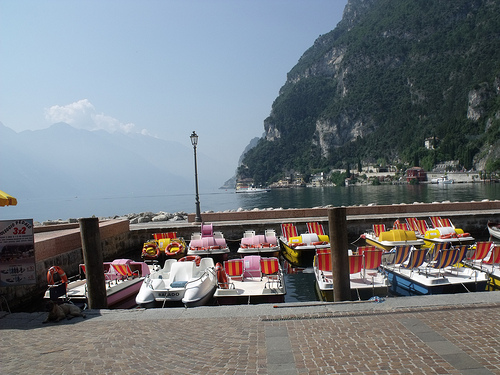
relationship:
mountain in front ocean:
[221, 1, 496, 188] [0, 186, 499, 217]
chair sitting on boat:
[217, 255, 252, 287] [207, 246, 296, 308]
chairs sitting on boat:
[259, 256, 281, 281] [207, 246, 296, 308]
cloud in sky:
[44, 97, 156, 136] [2, 3, 349, 191]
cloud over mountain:
[44, 97, 156, 136] [2, 120, 237, 220]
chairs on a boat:
[219, 250, 284, 282] [205, 255, 305, 305]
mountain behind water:
[221, 1, 496, 188] [2, 184, 497, 222]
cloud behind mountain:
[65, 101, 122, 131] [253, 19, 485, 144]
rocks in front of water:
[46, 199, 497, 222] [0, 178, 499, 221]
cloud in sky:
[44, 97, 156, 136] [1, 1, 349, 168]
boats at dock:
[41, 217, 498, 307] [0, 210, 499, 373]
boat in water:
[236, 183, 271, 195] [3, 172, 493, 215]